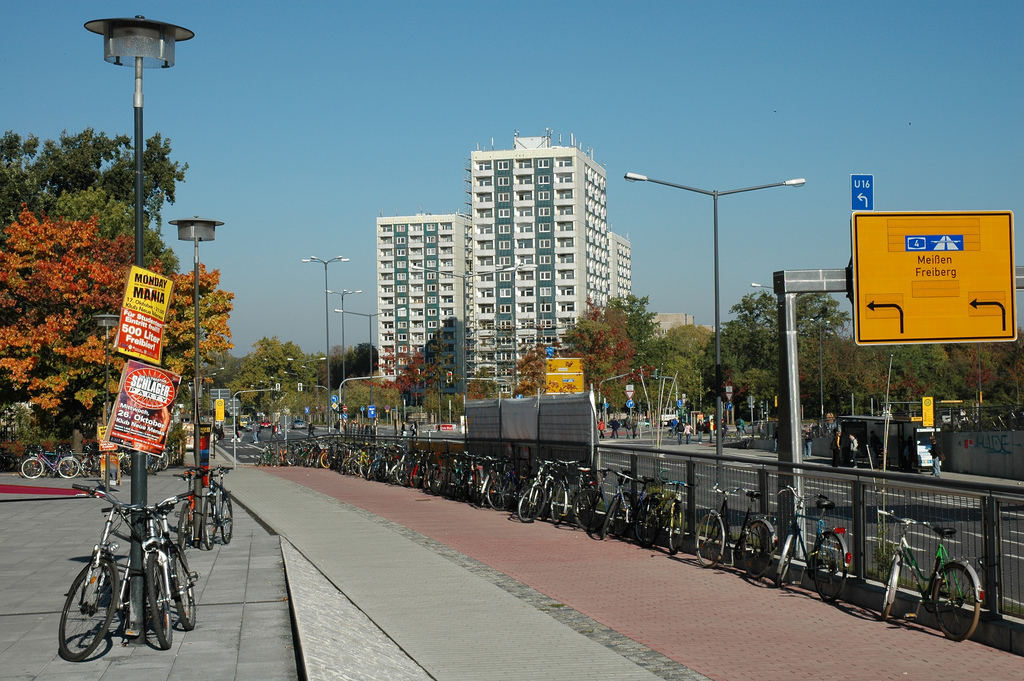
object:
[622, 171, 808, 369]
light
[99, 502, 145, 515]
seat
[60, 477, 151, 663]
bike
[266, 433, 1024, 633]
fence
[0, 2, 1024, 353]
sky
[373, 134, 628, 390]
buildings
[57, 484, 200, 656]
bikes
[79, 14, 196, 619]
pole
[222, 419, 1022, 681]
street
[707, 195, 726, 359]
pole